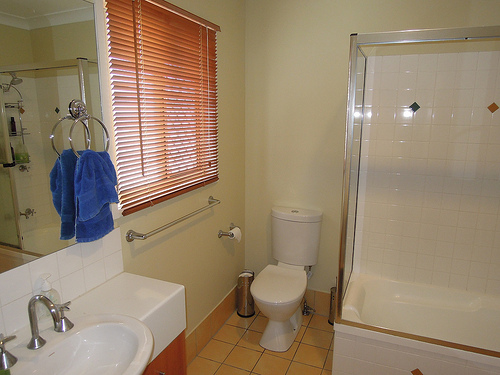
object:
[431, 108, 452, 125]
white tile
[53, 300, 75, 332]
dispenser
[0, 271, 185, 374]
counter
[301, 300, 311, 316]
toilet brush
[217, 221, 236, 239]
holder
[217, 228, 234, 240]
dispenser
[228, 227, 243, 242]
toilet paper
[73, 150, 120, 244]
towel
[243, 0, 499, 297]
wall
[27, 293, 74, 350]
faucet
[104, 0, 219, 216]
blinds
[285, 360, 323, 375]
tiles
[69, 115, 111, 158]
towel ring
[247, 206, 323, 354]
toilet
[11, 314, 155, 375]
sink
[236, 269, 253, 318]
container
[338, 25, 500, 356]
door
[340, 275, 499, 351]
bathtub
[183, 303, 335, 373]
floor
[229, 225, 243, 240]
roll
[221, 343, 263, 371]
pattern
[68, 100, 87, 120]
rack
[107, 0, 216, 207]
window